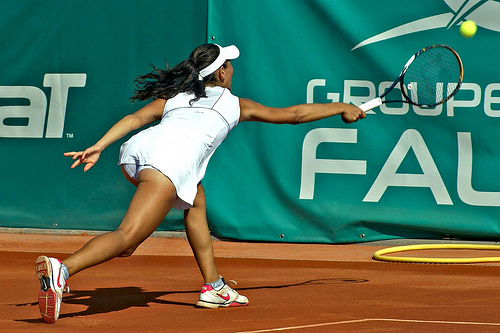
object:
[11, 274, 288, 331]
shadow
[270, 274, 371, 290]
shadow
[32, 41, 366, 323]
player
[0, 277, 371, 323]
shadow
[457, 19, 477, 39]
ball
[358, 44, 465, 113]
racket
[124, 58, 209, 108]
pony tail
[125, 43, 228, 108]
hair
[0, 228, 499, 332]
floor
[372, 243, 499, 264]
circle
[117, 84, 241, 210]
dress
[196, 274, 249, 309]
shoe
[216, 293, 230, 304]
symbol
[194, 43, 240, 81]
visor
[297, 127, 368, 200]
letter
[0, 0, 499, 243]
banner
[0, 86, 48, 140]
lettering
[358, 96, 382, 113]
handle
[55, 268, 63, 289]
sign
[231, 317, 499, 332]
line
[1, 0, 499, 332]
picture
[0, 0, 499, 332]
court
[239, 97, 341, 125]
arm